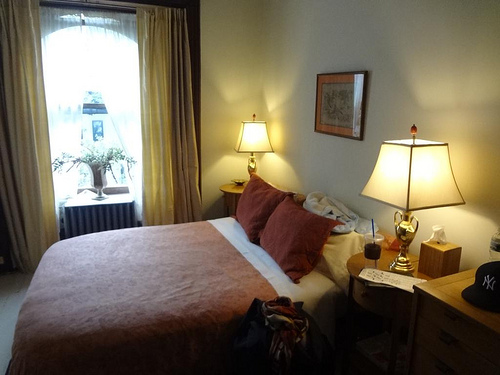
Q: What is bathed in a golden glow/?
A: A vase of flowers.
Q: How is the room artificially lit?
A: By 2 lamps.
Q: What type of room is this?
A: A bedroom.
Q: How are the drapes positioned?
A: Open.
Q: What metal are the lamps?
A: Brass.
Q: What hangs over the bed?
A: Framed art.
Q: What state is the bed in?
A: Made.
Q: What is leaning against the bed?
A: A back pack.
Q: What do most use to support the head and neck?
A: The pillows.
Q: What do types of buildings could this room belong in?
A: A house or a hotel.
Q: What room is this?
A: Bedroom.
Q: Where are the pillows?
A: On the bed.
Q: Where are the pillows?
A: On bed.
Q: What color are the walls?
A: White.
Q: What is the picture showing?
A: A bedroom.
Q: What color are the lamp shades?
A: White.